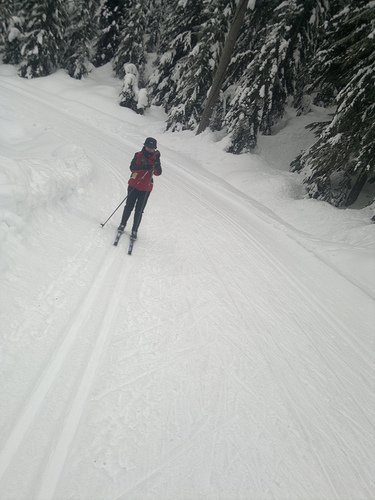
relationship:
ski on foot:
[126, 234, 135, 256] [130, 230, 135, 239]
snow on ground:
[152, 246, 245, 372] [2, 106, 371, 419]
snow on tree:
[126, 64, 149, 112] [118, 57, 160, 118]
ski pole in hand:
[109, 202, 124, 218] [155, 158, 159, 164]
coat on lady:
[128, 151, 154, 191] [116, 135, 162, 240]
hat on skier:
[145, 135, 157, 150] [115, 133, 164, 243]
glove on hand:
[142, 162, 148, 172] [142, 153, 161, 166]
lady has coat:
[116, 135, 162, 240] [128, 152, 161, 191]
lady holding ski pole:
[116, 135, 162, 240] [110, 193, 131, 217]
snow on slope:
[0, 64, 375, 500] [0, 63, 373, 497]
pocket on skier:
[129, 170, 138, 177] [98, 135, 163, 258]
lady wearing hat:
[116, 135, 162, 240] [143, 137, 157, 150]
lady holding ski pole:
[116, 135, 162, 240] [98, 130, 163, 257]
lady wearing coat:
[116, 135, 162, 240] [128, 152, 161, 191]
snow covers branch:
[126, 64, 148, 104] [125, 61, 135, 106]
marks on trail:
[18, 261, 173, 390] [80, 242, 366, 400]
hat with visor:
[131, 130, 162, 152] [143, 140, 157, 149]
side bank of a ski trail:
[3, 121, 91, 200] [16, 91, 301, 296]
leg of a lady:
[133, 189, 150, 233] [116, 136, 162, 242]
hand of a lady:
[153, 151, 158, 163] [116, 135, 162, 240]